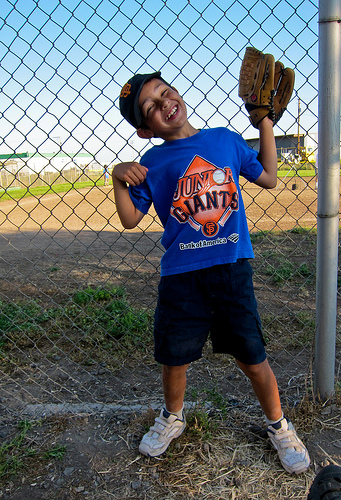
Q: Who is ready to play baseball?
A: The boy.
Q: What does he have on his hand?
A: Baseball glove.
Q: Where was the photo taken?
A: At a ball field.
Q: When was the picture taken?
A: Daytime.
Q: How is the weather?
A: Clear.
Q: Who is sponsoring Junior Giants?
A: Bank of America.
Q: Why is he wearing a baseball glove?
A: To help him catch baseballs.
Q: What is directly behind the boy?
A: Chain linked fence.